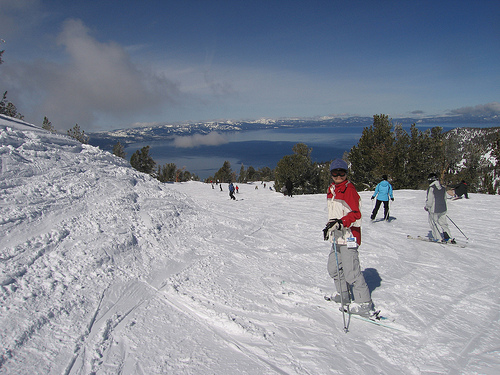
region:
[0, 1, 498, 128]
clouds in blue daytime sky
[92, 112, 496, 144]
snow capped mountains on horizon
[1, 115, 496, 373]
skiers on snow covered mountain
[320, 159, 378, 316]
woman with goggles on face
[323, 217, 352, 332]
gloved hand on ski pole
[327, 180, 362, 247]
red and white winter jacket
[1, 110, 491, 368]
a hill with snow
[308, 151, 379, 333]
person wearing a white and red jacket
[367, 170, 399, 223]
person with a blue jacket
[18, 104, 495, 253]
trees behind a field of snow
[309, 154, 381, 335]
person holding snowpoles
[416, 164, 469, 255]
two snow poles behind a person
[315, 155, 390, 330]
a shadow behind a man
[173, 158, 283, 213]
people ski on a snow field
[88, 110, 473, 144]
mountains on the background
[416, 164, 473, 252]
man wearing a gray and white jacket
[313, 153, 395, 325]
woman standing in snow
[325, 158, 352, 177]
woman wearing a hat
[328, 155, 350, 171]
woman's hat is blue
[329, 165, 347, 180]
woman wearing pair of goggles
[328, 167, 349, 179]
woman's goggles are black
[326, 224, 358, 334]
woman holding ski pole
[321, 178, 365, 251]
woman wearing a jacket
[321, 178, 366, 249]
jacket is red and white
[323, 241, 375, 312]
woman wearing pair of pants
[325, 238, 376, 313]
woman's pants are gray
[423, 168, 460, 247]
person on the snow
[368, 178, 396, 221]
person on the snow